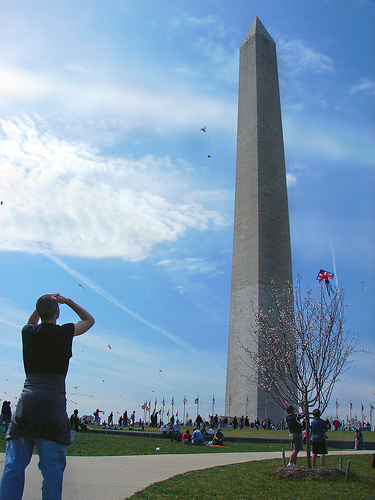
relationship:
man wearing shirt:
[1, 293, 96, 499] [21, 321, 76, 377]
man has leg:
[1, 293, 96, 499] [34, 436, 66, 499]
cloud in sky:
[1, 161, 229, 264] [1, 0, 373, 427]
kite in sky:
[315, 268, 337, 298] [1, 0, 373, 427]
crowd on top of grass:
[1, 408, 373, 444] [1, 425, 374, 500]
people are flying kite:
[284, 403, 329, 467] [315, 268, 337, 298]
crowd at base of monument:
[1, 408, 373, 444] [225, 15, 300, 427]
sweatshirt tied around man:
[5, 371, 72, 446] [1, 293, 96, 499]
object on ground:
[155, 446, 161, 453] [1, 424, 375, 499]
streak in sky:
[40, 250, 200, 356] [1, 0, 373, 427]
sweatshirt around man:
[5, 371, 72, 446] [1, 293, 96, 499]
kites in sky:
[66, 283, 163, 406] [1, 0, 373, 427]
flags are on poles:
[141, 395, 374, 411] [145, 394, 375, 429]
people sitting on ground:
[181, 427, 226, 446] [1, 424, 375, 499]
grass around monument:
[1, 425, 374, 500] [225, 15, 300, 427]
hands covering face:
[50, 293, 67, 304] [53, 296, 61, 319]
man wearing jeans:
[1, 293, 96, 499] [1, 438, 68, 499]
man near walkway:
[1, 293, 96, 499] [1, 449, 375, 498]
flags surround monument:
[141, 395, 374, 411] [225, 15, 300, 427]